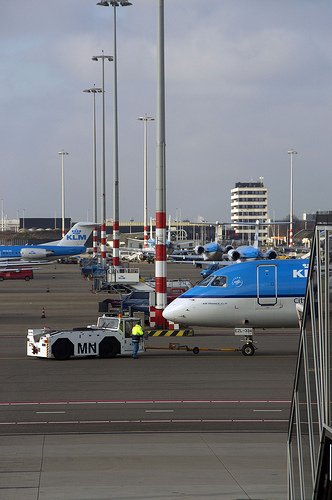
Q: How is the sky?
A: Overcast.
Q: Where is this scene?
A: Airport.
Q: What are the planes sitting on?
A: Tarmac.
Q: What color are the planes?
A: Blue and white.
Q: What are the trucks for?
A: Transport.